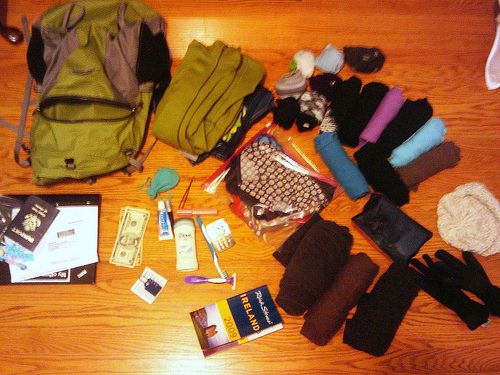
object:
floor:
[80, 297, 137, 337]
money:
[109, 206, 151, 268]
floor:
[58, 308, 141, 350]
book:
[188, 284, 282, 358]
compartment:
[37, 95, 134, 122]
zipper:
[132, 99, 144, 114]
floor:
[184, 0, 250, 38]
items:
[2, 3, 494, 373]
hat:
[435, 182, 500, 258]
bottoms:
[151, 39, 274, 167]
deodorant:
[173, 217, 198, 272]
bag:
[136, 167, 180, 202]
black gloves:
[434, 249, 499, 318]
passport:
[3, 194, 60, 252]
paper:
[0, 205, 99, 284]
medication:
[206, 217, 236, 252]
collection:
[271, 212, 425, 357]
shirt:
[261, 207, 359, 325]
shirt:
[389, 117, 447, 168]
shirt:
[300, 252, 379, 346]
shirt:
[359, 85, 405, 150]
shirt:
[353, 142, 410, 207]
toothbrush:
[196, 215, 229, 279]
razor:
[184, 273, 237, 290]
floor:
[429, 24, 464, 74]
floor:
[0, 0, 500, 375]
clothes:
[313, 76, 461, 207]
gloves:
[407, 254, 490, 331]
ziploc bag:
[224, 133, 338, 221]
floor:
[4, 290, 192, 374]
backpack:
[13, 0, 172, 188]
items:
[108, 143, 281, 316]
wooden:
[34, 292, 122, 367]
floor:
[30, 300, 106, 372]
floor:
[13, 303, 98, 373]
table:
[13, 306, 88, 373]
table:
[27, 316, 99, 365]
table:
[27, 300, 88, 372]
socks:
[361, 86, 461, 190]